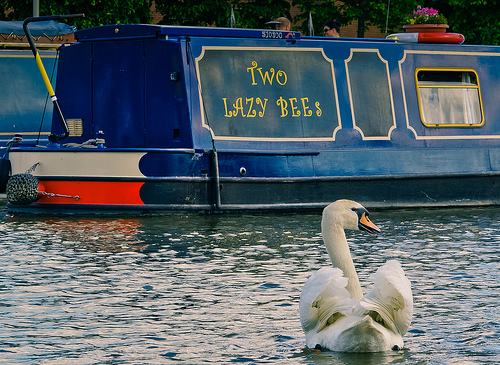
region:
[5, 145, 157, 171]
a white stripe on a boat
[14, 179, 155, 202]
a red stripe on a boat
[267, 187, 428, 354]
a white swan on the water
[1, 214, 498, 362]
water around a boat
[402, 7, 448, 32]
a poted plant on a boat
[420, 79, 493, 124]
a curtain in a window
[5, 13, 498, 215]
a large blue boat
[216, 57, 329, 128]
a boat name written in yellow on a boat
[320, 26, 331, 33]
sunglasses on a man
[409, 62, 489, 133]
a window on a boat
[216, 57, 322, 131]
Two Lazy Bees on the side of a boat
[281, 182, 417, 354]
a white swan in the water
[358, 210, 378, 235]
the orange beak of a swan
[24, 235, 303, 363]
rippling pond water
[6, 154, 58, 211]
a bundle of rope at the end of the boat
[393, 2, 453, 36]
pink flowers in a brown pot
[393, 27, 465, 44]
a red and white life preserver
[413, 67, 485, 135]
a partially opened side window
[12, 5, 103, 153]
a blue and yellow pole sticking out of the boat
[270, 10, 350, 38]
two mens' heads seen over the top of the boat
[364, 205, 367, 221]
beak of a bird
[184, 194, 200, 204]
bottom of boat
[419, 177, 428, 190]
side of a boat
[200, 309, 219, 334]
ripples of water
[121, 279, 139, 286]
part of the sea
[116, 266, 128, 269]
section of the ocean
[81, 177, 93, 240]
back part of a boat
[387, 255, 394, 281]
feathers of a bird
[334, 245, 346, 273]
neck of a bird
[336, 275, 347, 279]
white bird on water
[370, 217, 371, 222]
beak of a bird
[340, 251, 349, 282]
neck of a bird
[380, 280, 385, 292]
feathers of a bird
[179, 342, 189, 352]
ripples of moving water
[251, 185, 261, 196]
side of a boat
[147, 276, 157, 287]
section of the ocean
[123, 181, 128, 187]
red part on a boat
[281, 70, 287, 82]
name of a boat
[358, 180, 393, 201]
side of a boat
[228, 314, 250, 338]
ripples of ocean water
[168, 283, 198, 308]
part of ocean water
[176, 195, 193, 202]
bottom of a boat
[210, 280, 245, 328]
part of the ocean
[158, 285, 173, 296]
section of the sea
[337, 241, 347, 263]
neck of a bird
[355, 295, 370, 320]
back of a bird